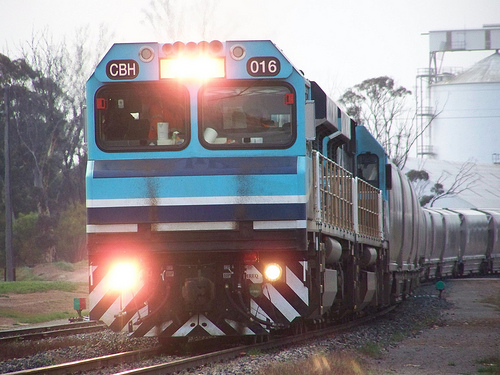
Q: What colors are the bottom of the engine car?
A: Black and white.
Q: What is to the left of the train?
A: Trees.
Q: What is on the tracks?
A: A train.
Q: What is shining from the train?
A: Headlights.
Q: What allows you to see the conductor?
A: 2 windows.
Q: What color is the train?
A: Blue.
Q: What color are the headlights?
A: Yellow.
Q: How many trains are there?
A: One.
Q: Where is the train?
A: On the tracks.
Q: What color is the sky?
A: Gray.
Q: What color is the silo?
A: White.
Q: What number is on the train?
A: Sixteen.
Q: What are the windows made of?
A: Glass.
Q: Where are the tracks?
A: Under the train.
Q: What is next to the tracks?
A: Gravel.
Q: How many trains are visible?
A: 1.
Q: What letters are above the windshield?
A: CBH.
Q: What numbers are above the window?
A: 016.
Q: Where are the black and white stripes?
A: Bottom front of train.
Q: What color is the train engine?
A: Light blue and dark blue.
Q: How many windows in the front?
A: 2.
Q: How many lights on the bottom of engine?
A: 2.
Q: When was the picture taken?
A: Daytime.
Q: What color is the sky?
A: White.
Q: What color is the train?
A: Blue.